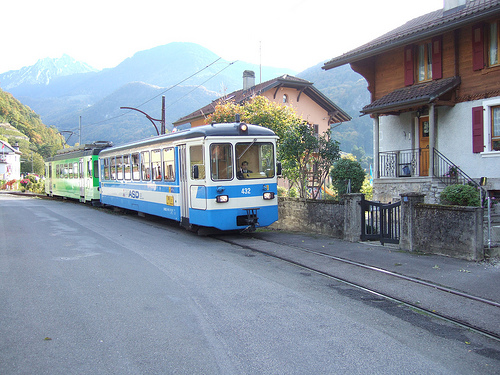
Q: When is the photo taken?
A: Daytime.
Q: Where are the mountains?
A: Behind the buildings.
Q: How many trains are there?
A: One.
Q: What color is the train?
A: Blue, green and white.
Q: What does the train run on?
A: A track.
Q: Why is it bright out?
A: It is sunny.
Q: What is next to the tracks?
A: The road.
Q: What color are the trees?
A: Green.